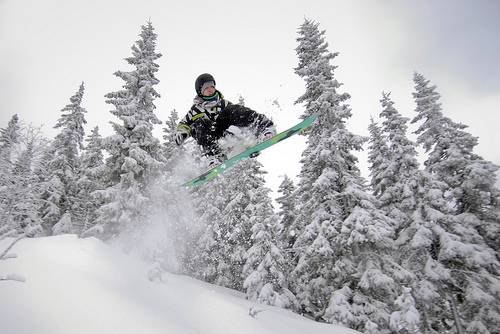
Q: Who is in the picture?
A: A boy.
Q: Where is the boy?
A: In the air.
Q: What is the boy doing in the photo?
A: Skiing.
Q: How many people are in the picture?
A: One.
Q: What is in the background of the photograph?
A: Trees.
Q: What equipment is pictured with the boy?
A: Skis.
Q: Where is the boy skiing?
A: Mountain slope.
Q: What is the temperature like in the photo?
A: Cold.